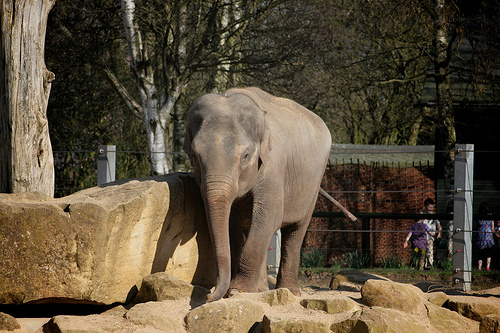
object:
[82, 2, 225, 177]
tree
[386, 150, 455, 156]
wire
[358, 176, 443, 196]
wire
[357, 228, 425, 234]
wire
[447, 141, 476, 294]
gray metal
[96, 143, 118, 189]
gray metal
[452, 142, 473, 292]
post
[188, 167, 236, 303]
trunk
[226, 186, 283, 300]
front leg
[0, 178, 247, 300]
rock wall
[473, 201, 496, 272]
girl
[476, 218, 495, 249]
dress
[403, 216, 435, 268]
child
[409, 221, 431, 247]
purple shirt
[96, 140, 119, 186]
post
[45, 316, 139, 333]
rocks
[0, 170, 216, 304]
rock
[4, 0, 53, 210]
tree trunk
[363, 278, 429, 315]
rock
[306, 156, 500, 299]
fence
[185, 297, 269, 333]
rocks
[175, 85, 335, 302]
elephant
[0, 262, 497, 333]
ground